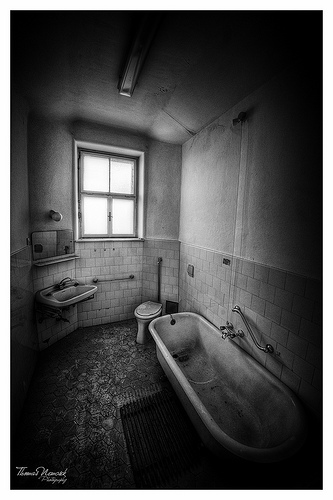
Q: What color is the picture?
A: Black and white.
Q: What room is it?
A: Bathroom.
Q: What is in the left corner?
A: Signature.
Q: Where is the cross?
A: Between window panes.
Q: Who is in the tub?
A: No one is in the tub.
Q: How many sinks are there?
A: One.